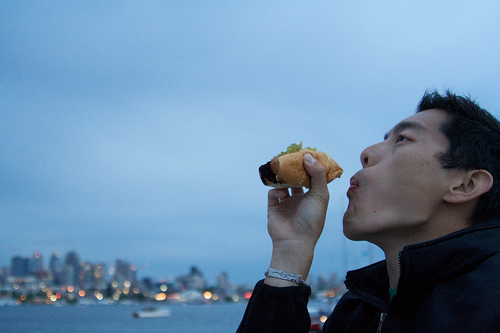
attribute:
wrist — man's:
[230, 242, 355, 300]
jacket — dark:
[222, 219, 483, 331]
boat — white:
[119, 291, 179, 329]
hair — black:
[408, 73, 498, 187]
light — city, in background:
[13, 240, 256, 309]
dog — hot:
[235, 142, 362, 196]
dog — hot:
[241, 131, 361, 198]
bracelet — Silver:
[263, 267, 306, 285]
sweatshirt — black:
[233, 220, 499, 330]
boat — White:
[134, 306, 174, 318]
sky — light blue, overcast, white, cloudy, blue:
[2, 0, 495, 285]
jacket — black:
[237, 225, 498, 328]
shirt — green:
[388, 290, 398, 299]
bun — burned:
[257, 150, 343, 190]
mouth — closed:
[347, 173, 364, 195]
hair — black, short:
[413, 87, 495, 225]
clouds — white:
[83, 108, 219, 224]